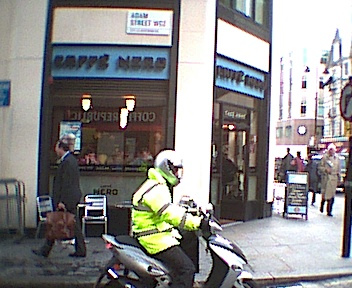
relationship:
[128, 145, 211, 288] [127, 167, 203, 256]
man wearing jacket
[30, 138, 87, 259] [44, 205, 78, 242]
man carrying bag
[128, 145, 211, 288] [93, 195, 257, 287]
man riding motorcycle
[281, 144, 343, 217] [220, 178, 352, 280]
people walking on sidewalk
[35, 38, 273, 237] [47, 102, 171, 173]
coffee shop has windows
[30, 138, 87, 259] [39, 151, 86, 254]
man wearing suit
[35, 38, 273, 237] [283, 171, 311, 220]
coffee shop showing menu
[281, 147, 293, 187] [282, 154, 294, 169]
people wearing jacket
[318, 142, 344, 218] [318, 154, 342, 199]
man wearing trench coat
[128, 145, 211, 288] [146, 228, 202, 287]
man wearing pants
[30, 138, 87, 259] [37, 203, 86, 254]
man wearing pants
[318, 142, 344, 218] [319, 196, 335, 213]
man wearing pants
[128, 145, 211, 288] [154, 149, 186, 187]
man wearing helmet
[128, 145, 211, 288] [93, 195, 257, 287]
man on motorcycle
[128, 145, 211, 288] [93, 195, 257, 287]
man sitting on motorcycle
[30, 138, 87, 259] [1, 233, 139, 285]
man walking down sidewalk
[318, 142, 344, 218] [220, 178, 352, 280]
man walking down sidewalk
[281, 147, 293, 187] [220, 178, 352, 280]
people walking down sidewalk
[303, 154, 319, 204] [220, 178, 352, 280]
man walking down sidewalk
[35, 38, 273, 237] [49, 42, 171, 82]
coffee shop has a sign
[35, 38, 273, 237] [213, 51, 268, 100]
coffee shop has a sign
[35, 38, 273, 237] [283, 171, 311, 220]
coffee shop has a menu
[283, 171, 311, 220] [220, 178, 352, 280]
menu on sidewalk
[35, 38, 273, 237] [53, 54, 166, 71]
coffee shop has a name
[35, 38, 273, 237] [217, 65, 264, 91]
coffee shop has a name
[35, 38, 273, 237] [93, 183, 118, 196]
coffee shop has a name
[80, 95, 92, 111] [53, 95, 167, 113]
light hanging from ceiling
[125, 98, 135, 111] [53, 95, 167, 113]
light hanging from ceiling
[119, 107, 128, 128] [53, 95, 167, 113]
light hanging from ceiling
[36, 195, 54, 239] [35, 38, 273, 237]
chair outside coffee shop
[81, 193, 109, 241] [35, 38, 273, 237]
chair outside coffee shop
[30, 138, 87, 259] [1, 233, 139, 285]
man walking on sidewalk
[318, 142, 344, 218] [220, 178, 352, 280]
man walking on sidewalk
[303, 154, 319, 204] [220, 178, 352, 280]
man walking on sidewalk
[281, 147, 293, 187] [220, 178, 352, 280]
people walking on sidewalk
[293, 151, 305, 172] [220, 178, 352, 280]
person walking on sidewalk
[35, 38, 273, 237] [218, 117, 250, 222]
coffee shop has a door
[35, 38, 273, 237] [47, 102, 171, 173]
coffee shop has a window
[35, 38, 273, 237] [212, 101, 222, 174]
coffee shop has a window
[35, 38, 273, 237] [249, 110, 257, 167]
coffee shop has a window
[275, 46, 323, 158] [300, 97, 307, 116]
building has a window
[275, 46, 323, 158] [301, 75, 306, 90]
building has a window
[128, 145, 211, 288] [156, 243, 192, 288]
man has a two legs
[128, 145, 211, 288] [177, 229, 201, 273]
man has a leg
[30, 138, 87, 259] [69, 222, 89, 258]
man has a two legs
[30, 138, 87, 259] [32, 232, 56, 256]
man has a leg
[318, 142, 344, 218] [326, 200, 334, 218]
man has a two legs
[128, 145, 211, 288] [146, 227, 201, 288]
man has two legs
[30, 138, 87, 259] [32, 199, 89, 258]
man has two legs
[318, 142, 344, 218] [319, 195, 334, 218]
man has two legs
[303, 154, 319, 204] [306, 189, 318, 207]
man has two legs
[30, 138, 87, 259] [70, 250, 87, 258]
man wearing shoe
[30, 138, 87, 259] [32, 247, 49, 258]
man wearing shoe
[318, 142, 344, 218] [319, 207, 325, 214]
man wearing shoe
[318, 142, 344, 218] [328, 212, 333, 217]
man wearing shoe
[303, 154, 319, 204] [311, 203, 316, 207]
man wearing shoe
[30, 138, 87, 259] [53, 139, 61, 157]
man has face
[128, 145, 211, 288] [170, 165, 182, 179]
man has face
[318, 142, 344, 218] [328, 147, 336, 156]
man has face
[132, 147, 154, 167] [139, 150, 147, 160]
man has face